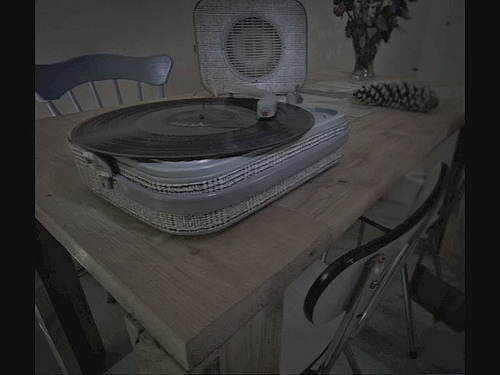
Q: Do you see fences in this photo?
A: No, there are no fences.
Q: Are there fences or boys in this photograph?
A: No, there are no fences or boys.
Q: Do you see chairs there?
A: Yes, there is a chair.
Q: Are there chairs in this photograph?
A: Yes, there is a chair.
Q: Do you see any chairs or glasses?
A: Yes, there is a chair.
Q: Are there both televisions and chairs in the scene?
A: No, there is a chair but no televisions.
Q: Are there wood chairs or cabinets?
A: Yes, there is a wood chair.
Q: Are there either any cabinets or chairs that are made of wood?
A: Yes, the chair is made of wood.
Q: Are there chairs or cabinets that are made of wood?
A: Yes, the chair is made of wood.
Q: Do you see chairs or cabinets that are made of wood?
A: Yes, the chair is made of wood.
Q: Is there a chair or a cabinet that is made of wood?
A: Yes, the chair is made of wood.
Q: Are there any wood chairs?
A: Yes, there is a wood chair.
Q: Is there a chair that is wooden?
A: Yes, there is a chair that is wooden.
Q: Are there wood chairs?
A: Yes, there is a chair that is made of wood.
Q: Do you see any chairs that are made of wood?
A: Yes, there is a chair that is made of wood.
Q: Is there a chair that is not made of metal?
A: Yes, there is a chair that is made of wood.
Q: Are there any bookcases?
A: No, there are no bookcases.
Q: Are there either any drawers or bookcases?
A: No, there are no bookcases or drawers.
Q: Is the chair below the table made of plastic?
A: No, the chair is made of wood.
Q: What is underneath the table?
A: The chair is underneath the table.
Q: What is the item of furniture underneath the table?
A: The piece of furniture is a chair.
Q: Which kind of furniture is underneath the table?
A: The piece of furniture is a chair.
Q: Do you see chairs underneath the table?
A: Yes, there is a chair underneath the table.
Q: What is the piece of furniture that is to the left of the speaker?
A: The piece of furniture is a chair.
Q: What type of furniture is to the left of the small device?
A: The piece of furniture is a chair.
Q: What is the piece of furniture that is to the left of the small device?
A: The piece of furniture is a chair.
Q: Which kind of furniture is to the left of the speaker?
A: The piece of furniture is a chair.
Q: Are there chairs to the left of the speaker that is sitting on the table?
A: Yes, there is a chair to the left of the speaker.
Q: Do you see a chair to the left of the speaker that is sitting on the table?
A: Yes, there is a chair to the left of the speaker.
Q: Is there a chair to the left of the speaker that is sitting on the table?
A: Yes, there is a chair to the left of the speaker.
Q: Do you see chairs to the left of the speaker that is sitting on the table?
A: Yes, there is a chair to the left of the speaker.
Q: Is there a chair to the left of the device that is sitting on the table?
A: Yes, there is a chair to the left of the speaker.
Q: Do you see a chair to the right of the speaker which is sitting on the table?
A: No, the chair is to the left of the speaker.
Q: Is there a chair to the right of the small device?
A: No, the chair is to the left of the speaker.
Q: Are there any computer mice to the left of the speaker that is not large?
A: No, there is a chair to the left of the speaker.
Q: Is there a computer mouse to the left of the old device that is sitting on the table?
A: No, there is a chair to the left of the speaker.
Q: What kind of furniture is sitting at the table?
A: The piece of furniture is a chair.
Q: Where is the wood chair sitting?
A: The chair is sitting at the table.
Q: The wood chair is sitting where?
A: The chair is sitting at the table.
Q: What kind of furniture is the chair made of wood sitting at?
A: The chair is sitting at the table.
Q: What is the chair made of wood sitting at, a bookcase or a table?
A: The chair is sitting at a table.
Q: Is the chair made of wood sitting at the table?
A: Yes, the chair is sitting at the table.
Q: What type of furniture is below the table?
A: The piece of furniture is a chair.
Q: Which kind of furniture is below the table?
A: The piece of furniture is a chair.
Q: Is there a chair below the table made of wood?
A: Yes, there is a chair below the table.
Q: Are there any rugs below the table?
A: No, there is a chair below the table.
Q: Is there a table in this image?
A: Yes, there is a table.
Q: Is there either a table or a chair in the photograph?
A: Yes, there is a table.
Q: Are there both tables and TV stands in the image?
A: No, there is a table but no TV stands.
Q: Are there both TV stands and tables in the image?
A: No, there is a table but no TV stands.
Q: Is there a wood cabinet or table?
A: Yes, there is a wood table.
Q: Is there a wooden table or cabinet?
A: Yes, there is a wood table.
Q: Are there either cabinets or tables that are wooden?
A: Yes, the table is wooden.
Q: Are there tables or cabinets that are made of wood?
A: Yes, the table is made of wood.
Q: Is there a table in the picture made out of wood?
A: Yes, there is a table that is made of wood.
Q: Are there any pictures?
A: No, there are no pictures.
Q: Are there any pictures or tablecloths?
A: No, there are no pictures or tablecloths.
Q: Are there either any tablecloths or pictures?
A: No, there are no pictures or tablecloths.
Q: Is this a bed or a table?
A: This is a table.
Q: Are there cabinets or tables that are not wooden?
A: No, there is a table but it is wooden.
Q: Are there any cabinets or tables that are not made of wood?
A: No, there is a table but it is made of wood.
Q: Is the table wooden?
A: Yes, the table is wooden.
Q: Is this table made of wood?
A: Yes, the table is made of wood.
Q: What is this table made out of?
A: The table is made of wood.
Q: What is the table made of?
A: The table is made of wood.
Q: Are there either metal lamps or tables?
A: No, there is a table but it is wooden.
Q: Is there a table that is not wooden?
A: No, there is a table but it is wooden.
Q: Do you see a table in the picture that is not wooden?
A: No, there is a table but it is wooden.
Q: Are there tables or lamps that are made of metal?
A: No, there is a table but it is made of wood.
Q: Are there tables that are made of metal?
A: No, there is a table but it is made of wood.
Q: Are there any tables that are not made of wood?
A: No, there is a table but it is made of wood.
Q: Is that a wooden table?
A: Yes, that is a wooden table.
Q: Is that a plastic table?
A: No, that is a wooden table.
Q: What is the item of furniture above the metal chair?
A: The piece of furniture is a table.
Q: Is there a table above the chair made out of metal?
A: Yes, there is a table above the chair.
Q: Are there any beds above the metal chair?
A: No, there is a table above the chair.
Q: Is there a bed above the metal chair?
A: No, there is a table above the chair.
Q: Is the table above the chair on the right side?
A: Yes, the table is above the chair.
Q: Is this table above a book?
A: No, the table is above the chair.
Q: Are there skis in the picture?
A: No, there are no skis.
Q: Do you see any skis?
A: No, there are no skis.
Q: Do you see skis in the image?
A: No, there are no skis.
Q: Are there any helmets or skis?
A: No, there are no skis or helmets.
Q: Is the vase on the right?
A: Yes, the vase is on the right of the image.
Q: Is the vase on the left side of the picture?
A: No, the vase is on the right of the image.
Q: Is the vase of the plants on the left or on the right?
A: The vase is on the right of the image.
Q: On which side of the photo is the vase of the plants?
A: The vase is on the right of the image.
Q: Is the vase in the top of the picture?
A: Yes, the vase is in the top of the image.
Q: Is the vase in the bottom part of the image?
A: No, the vase is in the top of the image.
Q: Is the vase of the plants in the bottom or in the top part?
A: The vase is in the top of the image.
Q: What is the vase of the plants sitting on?
A: The vase is sitting on the table.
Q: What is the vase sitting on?
A: The vase is sitting on the table.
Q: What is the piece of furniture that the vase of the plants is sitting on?
A: The piece of furniture is a table.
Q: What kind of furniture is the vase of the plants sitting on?
A: The vase is sitting on the table.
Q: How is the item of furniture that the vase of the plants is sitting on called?
A: The piece of furniture is a table.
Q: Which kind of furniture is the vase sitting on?
A: The vase is sitting on the table.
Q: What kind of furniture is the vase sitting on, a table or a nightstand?
A: The vase is sitting on a table.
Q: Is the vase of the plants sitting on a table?
A: Yes, the vase is sitting on a table.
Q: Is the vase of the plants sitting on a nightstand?
A: No, the vase is sitting on a table.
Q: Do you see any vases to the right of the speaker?
A: Yes, there is a vase to the right of the speaker.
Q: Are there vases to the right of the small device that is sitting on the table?
A: Yes, there is a vase to the right of the speaker.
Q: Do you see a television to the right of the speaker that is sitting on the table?
A: No, there is a vase to the right of the speaker.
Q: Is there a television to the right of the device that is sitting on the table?
A: No, there is a vase to the right of the speaker.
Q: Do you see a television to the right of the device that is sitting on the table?
A: No, there is a vase to the right of the speaker.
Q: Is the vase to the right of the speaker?
A: Yes, the vase is to the right of the speaker.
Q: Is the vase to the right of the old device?
A: Yes, the vase is to the right of the speaker.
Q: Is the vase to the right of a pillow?
A: No, the vase is to the right of the speaker.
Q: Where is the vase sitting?
A: The vase is sitting at the table.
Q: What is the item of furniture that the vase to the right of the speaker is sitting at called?
A: The piece of furniture is a table.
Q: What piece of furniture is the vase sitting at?
A: The vase is sitting at the table.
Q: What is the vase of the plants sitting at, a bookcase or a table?
A: The vase is sitting at a table.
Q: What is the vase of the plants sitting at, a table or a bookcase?
A: The vase is sitting at a table.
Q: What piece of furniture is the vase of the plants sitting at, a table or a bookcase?
A: The vase is sitting at a table.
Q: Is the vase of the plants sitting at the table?
A: Yes, the vase is sitting at the table.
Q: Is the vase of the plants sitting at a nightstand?
A: No, the vase is sitting at the table.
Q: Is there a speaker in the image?
A: Yes, there is a speaker.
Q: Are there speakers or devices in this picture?
A: Yes, there is a speaker.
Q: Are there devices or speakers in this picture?
A: Yes, there is a speaker.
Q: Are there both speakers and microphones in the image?
A: No, there is a speaker but no microphones.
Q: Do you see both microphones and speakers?
A: No, there is a speaker but no microphones.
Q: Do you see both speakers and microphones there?
A: No, there is a speaker but no microphones.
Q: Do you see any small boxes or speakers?
A: Yes, there is a small speaker.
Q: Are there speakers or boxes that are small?
A: Yes, the speaker is small.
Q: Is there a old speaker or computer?
A: Yes, there is an old speaker.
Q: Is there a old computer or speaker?
A: Yes, there is an old speaker.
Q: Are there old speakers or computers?
A: Yes, there is an old speaker.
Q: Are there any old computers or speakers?
A: Yes, there is an old speaker.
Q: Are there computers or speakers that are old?
A: Yes, the speaker is old.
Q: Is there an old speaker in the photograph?
A: Yes, there is an old speaker.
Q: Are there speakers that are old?
A: Yes, there is a speaker that is old.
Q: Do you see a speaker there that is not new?
A: Yes, there is a old speaker.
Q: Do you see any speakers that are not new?
A: Yes, there is a old speaker.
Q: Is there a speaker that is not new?
A: Yes, there is a old speaker.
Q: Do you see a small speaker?
A: Yes, there is a small speaker.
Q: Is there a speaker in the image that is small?
A: Yes, there is a speaker that is small.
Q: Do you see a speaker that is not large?
A: Yes, there is a small speaker.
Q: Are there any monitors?
A: No, there are no monitors.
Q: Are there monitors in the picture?
A: No, there are no monitors.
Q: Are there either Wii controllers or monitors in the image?
A: No, there are no monitors or Wii controllers.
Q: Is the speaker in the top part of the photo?
A: Yes, the speaker is in the top of the image.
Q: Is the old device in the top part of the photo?
A: Yes, the speaker is in the top of the image.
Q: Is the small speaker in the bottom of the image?
A: No, the speaker is in the top of the image.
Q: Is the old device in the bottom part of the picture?
A: No, the speaker is in the top of the image.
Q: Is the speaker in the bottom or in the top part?
A: The speaker is in the top of the image.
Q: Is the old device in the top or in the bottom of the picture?
A: The speaker is in the top of the image.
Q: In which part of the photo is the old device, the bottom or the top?
A: The speaker is in the top of the image.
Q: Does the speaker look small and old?
A: Yes, the speaker is small and old.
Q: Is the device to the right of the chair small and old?
A: Yes, the speaker is small and old.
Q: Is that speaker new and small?
A: No, the speaker is small but old.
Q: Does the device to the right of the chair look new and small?
A: No, the speaker is small but old.